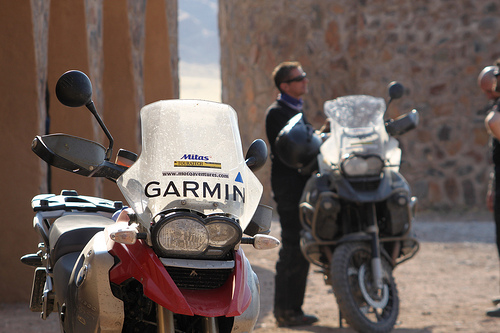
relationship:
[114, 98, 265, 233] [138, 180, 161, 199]
plastic has letter g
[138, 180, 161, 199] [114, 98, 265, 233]
letter g on plastic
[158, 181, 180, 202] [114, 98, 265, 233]
letter a on plastic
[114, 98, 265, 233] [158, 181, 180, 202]
plastic has letter a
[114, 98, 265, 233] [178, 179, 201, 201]
plastic has letter r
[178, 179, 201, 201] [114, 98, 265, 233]
letter r on plastic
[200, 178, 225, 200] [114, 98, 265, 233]
letter m on plastic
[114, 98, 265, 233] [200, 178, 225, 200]
plastic has letter m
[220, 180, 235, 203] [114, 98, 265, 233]
letter i on plastic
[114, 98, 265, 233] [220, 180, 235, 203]
plastic has letter i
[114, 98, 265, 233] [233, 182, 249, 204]
plastic has letter n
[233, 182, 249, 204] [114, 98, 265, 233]
letter n on plastic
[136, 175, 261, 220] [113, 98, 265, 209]
word "garmin printed on plastic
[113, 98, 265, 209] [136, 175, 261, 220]
plastic has word "garmin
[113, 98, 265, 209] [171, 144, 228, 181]
plastic has "mitas" logo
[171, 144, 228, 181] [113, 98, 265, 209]
"mitas" logo on plastic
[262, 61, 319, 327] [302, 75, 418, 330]
man standing next to motorcycle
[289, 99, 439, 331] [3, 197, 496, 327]
black motorcycle on ground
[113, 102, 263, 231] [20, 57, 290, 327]
white wind shield on bike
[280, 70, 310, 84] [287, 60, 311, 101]
sun glasses on face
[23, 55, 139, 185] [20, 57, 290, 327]
side mirror on bike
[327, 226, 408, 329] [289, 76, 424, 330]
tire on bike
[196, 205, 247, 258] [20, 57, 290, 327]
head light on bike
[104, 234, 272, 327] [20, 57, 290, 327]
fender on bike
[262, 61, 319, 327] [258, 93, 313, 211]
man wearing black jacket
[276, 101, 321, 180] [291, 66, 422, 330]
helmet hanging on motorcycle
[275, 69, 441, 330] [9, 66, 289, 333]
motorcycle leaning on its kickstand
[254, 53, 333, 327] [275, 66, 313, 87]
man wearing sunglasses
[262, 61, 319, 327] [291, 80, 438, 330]
man standing next to motorcycle